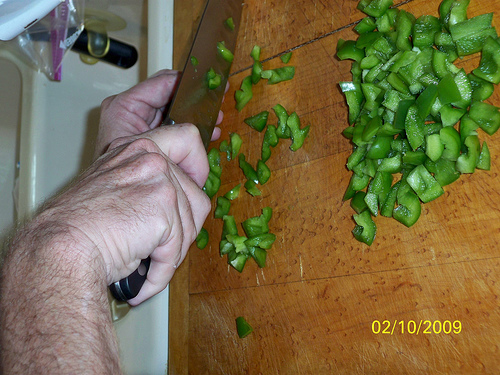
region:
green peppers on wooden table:
[287, 2, 497, 252]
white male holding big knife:
[0, 0, 260, 360]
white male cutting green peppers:
[0, 30, 310, 370]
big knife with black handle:
[95, 15, 250, 305]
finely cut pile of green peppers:
[325, 0, 490, 250]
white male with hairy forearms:
[5, 115, 220, 370]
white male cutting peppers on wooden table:
[5, 10, 255, 370]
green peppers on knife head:
[146, 2, 251, 167]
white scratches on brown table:
[167, 246, 312, 371]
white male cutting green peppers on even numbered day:
[1, 0, 492, 372]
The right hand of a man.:
[42, 67, 214, 309]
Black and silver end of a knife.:
[107, 253, 152, 305]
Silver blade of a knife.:
[165, 1, 242, 152]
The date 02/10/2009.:
[371, 319, 461, 334]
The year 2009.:
[423, 320, 461, 333]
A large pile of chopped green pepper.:
[336, 3, 498, 246]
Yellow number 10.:
[398, 319, 416, 335]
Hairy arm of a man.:
[1, 223, 123, 374]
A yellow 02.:
[370, 318, 391, 333]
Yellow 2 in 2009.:
[423, 319, 432, 333]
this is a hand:
[82, 137, 198, 285]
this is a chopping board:
[285, 272, 409, 364]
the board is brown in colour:
[282, 293, 352, 365]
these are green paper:
[355, 17, 403, 125]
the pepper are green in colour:
[349, 35, 459, 154]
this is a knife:
[192, 50, 222, 92]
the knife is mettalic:
[180, 86, 208, 126]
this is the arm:
[5, 260, 98, 373]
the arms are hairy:
[10, 290, 90, 363]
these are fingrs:
[141, 131, 191, 231]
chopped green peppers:
[322, 1, 499, 251]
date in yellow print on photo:
[361, 314, 471, 346]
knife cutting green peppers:
[98, 0, 317, 317]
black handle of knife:
[96, 238, 161, 301]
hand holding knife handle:
[8, 3, 249, 373]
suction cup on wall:
[73, 8, 130, 62]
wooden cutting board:
[163, 0, 495, 372]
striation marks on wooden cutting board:
[311, 254, 468, 301]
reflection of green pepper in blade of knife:
[180, 80, 212, 120]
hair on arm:
[10, 275, 62, 340]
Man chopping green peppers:
[1, 0, 249, 374]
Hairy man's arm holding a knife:
[1, 65, 227, 370]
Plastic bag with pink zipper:
[3, 0, 88, 85]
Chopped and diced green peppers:
[330, 0, 497, 242]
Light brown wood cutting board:
[170, 2, 499, 372]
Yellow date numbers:
[367, 317, 464, 337]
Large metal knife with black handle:
[105, 0, 246, 301]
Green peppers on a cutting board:
[332, 0, 499, 249]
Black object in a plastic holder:
[34, 5, 139, 70]